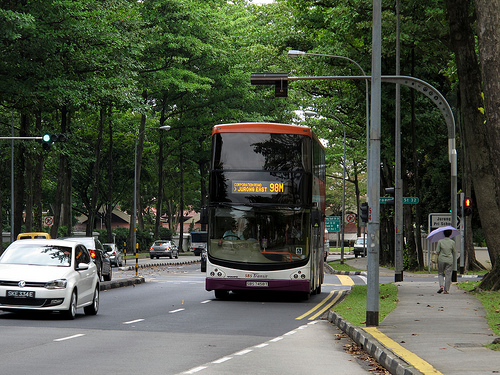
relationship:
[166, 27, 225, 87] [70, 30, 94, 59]
leaves ear green